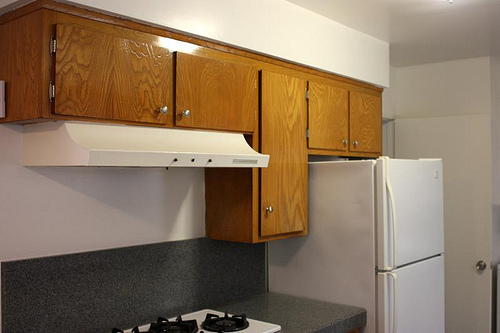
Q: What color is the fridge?
A: White.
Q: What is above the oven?
A: Vent.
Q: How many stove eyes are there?
A: Three.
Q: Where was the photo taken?
A: Kitchen.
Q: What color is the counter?
A: Grey.